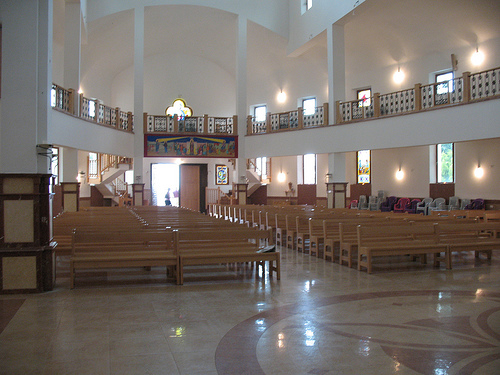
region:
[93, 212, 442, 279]
several wooden church pews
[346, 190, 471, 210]
plastic chairs against a wall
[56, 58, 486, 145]
a balcony in a church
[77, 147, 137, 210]
stairs going up to balcony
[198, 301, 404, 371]
a tile floor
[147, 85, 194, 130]
a window with decorative glass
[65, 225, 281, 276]
a wooden church pew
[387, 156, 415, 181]
a light mounted to the wall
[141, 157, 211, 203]
church door open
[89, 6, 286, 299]
a church with a high cieling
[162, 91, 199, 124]
stained glass window above balcony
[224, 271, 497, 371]
large red design on floor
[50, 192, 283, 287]
row of wooden benches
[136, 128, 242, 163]
painting hanging above building doorway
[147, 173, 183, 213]
person standing in doorway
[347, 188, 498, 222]
row of plastic chairs along wall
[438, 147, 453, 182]
tree with green leaves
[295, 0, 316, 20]
window on ceiling of building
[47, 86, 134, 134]
brown wooden balcony rails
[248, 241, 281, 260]
piece of clothing on wooden bench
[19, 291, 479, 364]
clean shiny floor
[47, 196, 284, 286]
rows of wooden benches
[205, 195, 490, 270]
rows of wooden benches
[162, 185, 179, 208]
person standing by door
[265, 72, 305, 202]
artificial light is on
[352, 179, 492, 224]
chairs stacked and lined up against wall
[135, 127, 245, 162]
artwork on white wall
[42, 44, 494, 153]
second floor with multiple windows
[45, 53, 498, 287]
building is empty inside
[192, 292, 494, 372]
floor decorated with tile mosaic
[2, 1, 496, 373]
the inside of a church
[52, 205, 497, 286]
pews inside the church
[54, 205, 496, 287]
pews for the congregation and visitors to sit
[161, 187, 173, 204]
a person outside of the church's doors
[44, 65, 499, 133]
the upper level for the congregation to sit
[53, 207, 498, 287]
wooden benches inside the church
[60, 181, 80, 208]
a wooden podium in the back of the church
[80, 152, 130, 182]
stair case to enter the upper level of the church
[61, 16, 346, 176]
four white beams to hold the church building structure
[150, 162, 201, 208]
an opened door to the front of the church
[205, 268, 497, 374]
large design on floor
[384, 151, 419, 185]
light on wall of building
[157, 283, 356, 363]
light reflecting on tile floor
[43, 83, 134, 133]
wooden balcony railing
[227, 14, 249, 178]
white building support pillar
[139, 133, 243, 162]
painting on balcony wall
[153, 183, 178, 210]
person standing in building doorway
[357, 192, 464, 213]
row of plastic chairs along wall